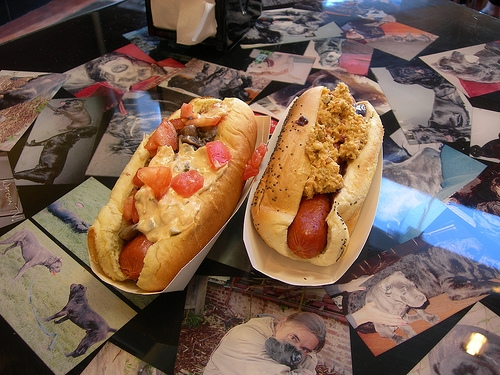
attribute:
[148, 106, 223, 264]
hotdog — cooked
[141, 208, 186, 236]
cheese — orange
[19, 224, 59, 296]
dog — brown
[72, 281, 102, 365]
dog — black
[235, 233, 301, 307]
holder — white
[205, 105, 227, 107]
mayonnaise — white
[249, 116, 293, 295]
container — cardboard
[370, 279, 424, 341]
dog — small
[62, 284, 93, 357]
dog — standing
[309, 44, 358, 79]
dog — sitting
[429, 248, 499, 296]
dog — asleep